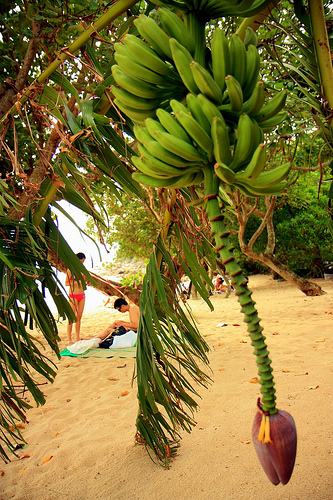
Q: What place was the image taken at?
A: It was taken at the beach.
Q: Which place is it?
A: It is a beach.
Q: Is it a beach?
A: Yes, it is a beach.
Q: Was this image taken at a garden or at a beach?
A: It was taken at a beach.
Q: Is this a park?
A: No, it is a beach.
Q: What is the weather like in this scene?
A: It is clear.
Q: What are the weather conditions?
A: It is clear.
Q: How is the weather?
A: It is clear.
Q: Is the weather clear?
A: Yes, it is clear.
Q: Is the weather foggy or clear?
A: It is clear.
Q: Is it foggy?
A: No, it is clear.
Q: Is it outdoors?
A: Yes, it is outdoors.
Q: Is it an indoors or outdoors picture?
A: It is outdoors.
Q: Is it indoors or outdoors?
A: It is outdoors.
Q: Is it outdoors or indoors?
A: It is outdoors.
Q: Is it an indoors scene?
A: No, it is outdoors.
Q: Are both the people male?
A: No, they are both male and female.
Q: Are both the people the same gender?
A: No, they are both male and female.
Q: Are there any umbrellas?
A: No, there are no umbrellas.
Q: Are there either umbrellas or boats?
A: No, there are no umbrellas or boats.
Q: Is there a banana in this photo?
A: Yes, there is a banana.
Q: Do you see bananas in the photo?
A: Yes, there is a banana.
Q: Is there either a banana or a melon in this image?
A: Yes, there is a banana.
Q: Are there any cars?
A: No, there are no cars.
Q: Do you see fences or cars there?
A: No, there are no cars or fences.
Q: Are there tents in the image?
A: No, there are no tents.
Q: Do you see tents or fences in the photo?
A: No, there are no tents or fences.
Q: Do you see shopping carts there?
A: No, there are no shopping carts.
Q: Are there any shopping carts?
A: No, there are no shopping carts.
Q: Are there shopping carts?
A: No, there are no shopping carts.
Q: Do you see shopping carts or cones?
A: No, there are no shopping carts or cones.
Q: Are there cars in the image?
A: No, there are no cars.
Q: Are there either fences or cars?
A: No, there are no cars or fences.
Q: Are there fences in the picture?
A: No, there are no fences.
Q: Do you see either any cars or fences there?
A: No, there are no fences or cars.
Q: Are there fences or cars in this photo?
A: No, there are no fences or cars.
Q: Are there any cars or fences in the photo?
A: No, there are no fences or cars.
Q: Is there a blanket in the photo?
A: Yes, there is a blanket.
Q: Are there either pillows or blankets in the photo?
A: Yes, there is a blanket.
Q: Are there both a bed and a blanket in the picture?
A: No, there is a blanket but no beds.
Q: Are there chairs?
A: No, there are no chairs.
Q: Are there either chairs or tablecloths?
A: No, there are no chairs or tablecloths.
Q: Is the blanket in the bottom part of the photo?
A: Yes, the blanket is in the bottom of the image.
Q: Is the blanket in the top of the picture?
A: No, the blanket is in the bottom of the image.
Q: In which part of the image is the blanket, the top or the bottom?
A: The blanket is in the bottom of the image.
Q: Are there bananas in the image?
A: Yes, there are bananas.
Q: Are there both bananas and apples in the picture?
A: No, there are bananas but no apples.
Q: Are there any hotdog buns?
A: No, there are no hotdog buns.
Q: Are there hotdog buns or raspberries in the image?
A: No, there are no hotdog buns or raspberries.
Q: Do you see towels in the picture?
A: Yes, there is a towel.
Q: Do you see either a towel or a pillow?
A: Yes, there is a towel.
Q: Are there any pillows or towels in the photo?
A: Yes, there is a towel.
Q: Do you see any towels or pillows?
A: Yes, there is a towel.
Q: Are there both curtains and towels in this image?
A: No, there is a towel but no curtains.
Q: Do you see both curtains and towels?
A: No, there is a towel but no curtains.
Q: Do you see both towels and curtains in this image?
A: No, there is a towel but no curtains.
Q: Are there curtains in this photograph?
A: No, there are no curtains.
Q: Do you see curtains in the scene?
A: No, there are no curtains.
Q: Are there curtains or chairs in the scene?
A: No, there are no curtains or chairs.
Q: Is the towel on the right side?
A: No, the towel is on the left of the image.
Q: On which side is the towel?
A: The towel is on the left of the image.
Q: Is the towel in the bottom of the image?
A: Yes, the towel is in the bottom of the image.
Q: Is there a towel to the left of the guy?
A: Yes, there is a towel to the left of the guy.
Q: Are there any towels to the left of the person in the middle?
A: Yes, there is a towel to the left of the guy.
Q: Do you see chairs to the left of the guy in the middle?
A: No, there is a towel to the left of the guy.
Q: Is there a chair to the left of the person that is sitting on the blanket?
A: No, there is a towel to the left of the guy.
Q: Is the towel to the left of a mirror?
A: No, the towel is to the left of a guy.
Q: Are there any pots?
A: No, there are no pots.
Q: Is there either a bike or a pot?
A: No, there are no pots or bikes.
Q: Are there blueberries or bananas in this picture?
A: Yes, there is a banana.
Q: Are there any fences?
A: No, there are no fences.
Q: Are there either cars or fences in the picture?
A: No, there are no fences or cars.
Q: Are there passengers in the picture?
A: No, there are no passengers.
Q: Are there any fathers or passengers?
A: No, there are no passengers or fathers.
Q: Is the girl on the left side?
A: Yes, the girl is on the left of the image.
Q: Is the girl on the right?
A: No, the girl is on the left of the image.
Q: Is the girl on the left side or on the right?
A: The girl is on the left of the image.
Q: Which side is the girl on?
A: The girl is on the left of the image.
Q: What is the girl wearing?
A: The girl is wearing a bikini.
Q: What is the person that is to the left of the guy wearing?
A: The girl is wearing a bikini.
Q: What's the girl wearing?
A: The girl is wearing a bikini.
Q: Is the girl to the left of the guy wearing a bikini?
A: Yes, the girl is wearing a bikini.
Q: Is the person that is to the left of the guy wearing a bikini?
A: Yes, the girl is wearing a bikini.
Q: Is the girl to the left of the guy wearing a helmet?
A: No, the girl is wearing a bikini.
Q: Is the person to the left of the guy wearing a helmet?
A: No, the girl is wearing a bikini.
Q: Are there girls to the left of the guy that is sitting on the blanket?
A: Yes, there is a girl to the left of the guy.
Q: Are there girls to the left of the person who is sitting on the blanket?
A: Yes, there is a girl to the left of the guy.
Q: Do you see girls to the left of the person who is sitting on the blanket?
A: Yes, there is a girl to the left of the guy.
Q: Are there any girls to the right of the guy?
A: No, the girl is to the left of the guy.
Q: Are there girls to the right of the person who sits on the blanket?
A: No, the girl is to the left of the guy.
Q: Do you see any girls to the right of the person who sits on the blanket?
A: No, the girl is to the left of the guy.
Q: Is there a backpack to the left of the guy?
A: No, there is a girl to the left of the guy.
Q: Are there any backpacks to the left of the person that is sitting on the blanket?
A: No, there is a girl to the left of the guy.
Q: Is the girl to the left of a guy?
A: Yes, the girl is to the left of a guy.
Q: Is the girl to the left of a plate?
A: No, the girl is to the left of a guy.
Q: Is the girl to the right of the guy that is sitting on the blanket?
A: No, the girl is to the left of the guy.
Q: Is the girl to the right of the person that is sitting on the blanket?
A: No, the girl is to the left of the guy.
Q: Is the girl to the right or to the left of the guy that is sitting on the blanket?
A: The girl is to the left of the guy.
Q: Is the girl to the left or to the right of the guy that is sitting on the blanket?
A: The girl is to the left of the guy.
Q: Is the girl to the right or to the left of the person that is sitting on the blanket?
A: The girl is to the left of the guy.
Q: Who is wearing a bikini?
A: The girl is wearing a bikini.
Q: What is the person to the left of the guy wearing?
A: The girl is wearing a bikini.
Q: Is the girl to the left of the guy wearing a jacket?
A: No, the girl is wearing a bikini.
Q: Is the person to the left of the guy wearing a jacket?
A: No, the girl is wearing a bikini.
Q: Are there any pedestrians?
A: No, there are no pedestrians.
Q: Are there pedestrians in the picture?
A: No, there are no pedestrians.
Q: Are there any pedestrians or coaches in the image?
A: No, there are no pedestrians or coaches.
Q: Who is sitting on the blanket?
A: The guy is sitting on the blanket.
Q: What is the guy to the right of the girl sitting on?
A: The guy is sitting on the blanket.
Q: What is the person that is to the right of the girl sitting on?
A: The guy is sitting on the blanket.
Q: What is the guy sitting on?
A: The guy is sitting on the blanket.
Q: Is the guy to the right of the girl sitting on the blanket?
A: Yes, the guy is sitting on the blanket.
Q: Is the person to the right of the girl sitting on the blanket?
A: Yes, the guy is sitting on the blanket.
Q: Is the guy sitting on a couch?
A: No, the guy is sitting on the blanket.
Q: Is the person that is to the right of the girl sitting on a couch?
A: No, the guy is sitting on the blanket.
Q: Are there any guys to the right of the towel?
A: Yes, there is a guy to the right of the towel.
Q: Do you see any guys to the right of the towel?
A: Yes, there is a guy to the right of the towel.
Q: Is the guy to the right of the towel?
A: Yes, the guy is to the right of the towel.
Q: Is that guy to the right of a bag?
A: No, the guy is to the right of the towel.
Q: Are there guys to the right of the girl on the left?
A: Yes, there is a guy to the right of the girl.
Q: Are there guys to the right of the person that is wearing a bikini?
A: Yes, there is a guy to the right of the girl.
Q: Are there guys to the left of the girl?
A: No, the guy is to the right of the girl.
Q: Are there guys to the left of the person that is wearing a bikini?
A: No, the guy is to the right of the girl.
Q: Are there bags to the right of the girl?
A: No, there is a guy to the right of the girl.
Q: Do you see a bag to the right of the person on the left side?
A: No, there is a guy to the right of the girl.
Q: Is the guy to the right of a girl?
A: Yes, the guy is to the right of a girl.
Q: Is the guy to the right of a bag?
A: No, the guy is to the right of a girl.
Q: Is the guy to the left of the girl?
A: No, the guy is to the right of the girl.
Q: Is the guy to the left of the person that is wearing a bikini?
A: No, the guy is to the right of the girl.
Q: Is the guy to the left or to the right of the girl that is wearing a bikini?
A: The guy is to the right of the girl.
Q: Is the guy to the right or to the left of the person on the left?
A: The guy is to the right of the girl.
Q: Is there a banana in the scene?
A: Yes, there are bananas.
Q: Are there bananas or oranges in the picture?
A: Yes, there are bananas.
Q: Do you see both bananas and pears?
A: No, there are bananas but no pears.